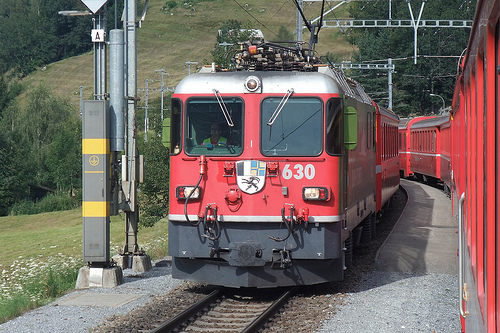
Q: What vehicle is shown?
A: Train.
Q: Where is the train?
A: Tracks.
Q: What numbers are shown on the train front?
A: 630.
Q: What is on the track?
A: A train.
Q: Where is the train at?
A: A station.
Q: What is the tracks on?
A: Gravel.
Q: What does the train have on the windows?
A: Wipers.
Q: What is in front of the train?
A: Tracks.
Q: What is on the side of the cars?
A: Handles.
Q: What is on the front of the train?
A: 630.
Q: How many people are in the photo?
A: One.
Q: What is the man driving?
A: A train.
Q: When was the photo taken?
A: Daytime.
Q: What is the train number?
A: 630.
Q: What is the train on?
A: Tracks.